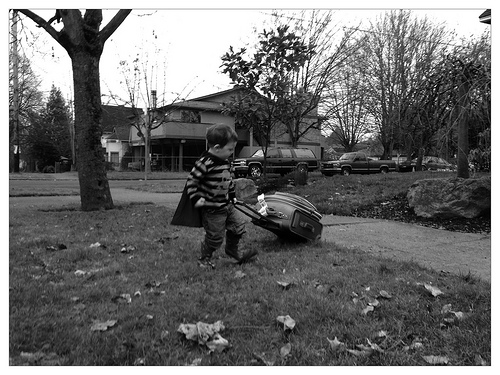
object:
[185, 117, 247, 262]
boy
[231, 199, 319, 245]
trolley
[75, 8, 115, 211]
tree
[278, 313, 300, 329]
leaves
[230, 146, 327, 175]
wagon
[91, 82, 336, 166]
house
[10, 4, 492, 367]
background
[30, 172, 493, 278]
sidewalk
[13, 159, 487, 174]
street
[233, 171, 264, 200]
bag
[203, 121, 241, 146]
hair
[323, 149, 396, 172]
cars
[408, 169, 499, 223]
rock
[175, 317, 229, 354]
leaf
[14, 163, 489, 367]
ground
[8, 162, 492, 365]
yard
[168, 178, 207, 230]
cape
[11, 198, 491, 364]
grass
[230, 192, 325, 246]
suitcase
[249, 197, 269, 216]
tag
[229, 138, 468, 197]
parked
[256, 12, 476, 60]
wire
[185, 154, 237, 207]
shirt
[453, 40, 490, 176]
trees